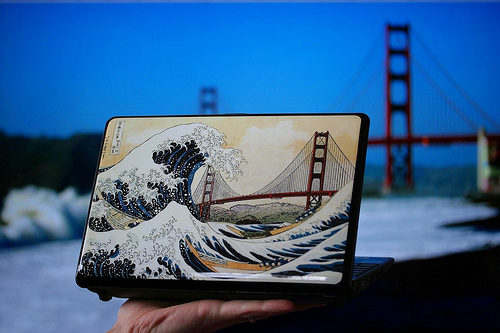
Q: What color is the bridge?
A: Red.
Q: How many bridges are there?
A: One.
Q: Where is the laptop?
A: Ledge.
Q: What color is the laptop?
A: Black.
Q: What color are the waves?
A: White.